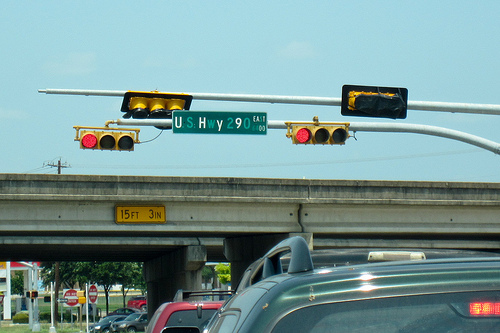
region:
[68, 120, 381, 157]
traffic lights are red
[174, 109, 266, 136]
road sign is green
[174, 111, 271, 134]
road sign is white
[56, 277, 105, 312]
sign under bridge is red and white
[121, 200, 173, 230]
sign on bridge is yellow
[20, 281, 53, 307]
pedestrian signs under bridge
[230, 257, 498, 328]
green van under traffic light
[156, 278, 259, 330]
red van under traffic light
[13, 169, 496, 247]
overpass is grey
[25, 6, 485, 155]
sky is mostly overcast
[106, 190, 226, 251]
Yellow sign on overpass.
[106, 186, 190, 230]
Black writing on yellow sign.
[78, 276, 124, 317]
Red and white do not enter sign.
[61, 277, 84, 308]
Red and white do not enter sign.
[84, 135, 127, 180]
Traffic light is on red.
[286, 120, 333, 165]
Traffic signal is on red light.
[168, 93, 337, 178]
Green and white street sign on pole.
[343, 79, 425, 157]
Traffic light is covered with black covering.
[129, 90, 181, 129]
Traffic light is covered with black cover.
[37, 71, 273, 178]
Sky is blue and clear.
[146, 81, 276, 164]
a street sign on a pole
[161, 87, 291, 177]
a street sign in the air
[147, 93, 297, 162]
a street sign on a metal pole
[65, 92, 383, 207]
a street sign in between two lights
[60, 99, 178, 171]
a traffic light in the air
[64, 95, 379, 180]
two traffic lights in the air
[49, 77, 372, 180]
two red traffic lights in the air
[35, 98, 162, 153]
a traffic light on a pole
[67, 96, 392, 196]
two traffic lights on a pole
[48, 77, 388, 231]
two traffic lights on a metal pole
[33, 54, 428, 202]
street lights attached to pole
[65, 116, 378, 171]
the streetlights are yellow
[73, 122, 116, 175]
the light is red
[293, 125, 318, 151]
the light is red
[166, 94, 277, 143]
the sign is green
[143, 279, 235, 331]
the car is red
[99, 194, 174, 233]
the sign is yellow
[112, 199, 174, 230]
black letters on sign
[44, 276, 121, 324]
signs are red and white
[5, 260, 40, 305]
the building is white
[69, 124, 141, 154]
an electric traffic signal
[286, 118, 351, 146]
an electric traffic signal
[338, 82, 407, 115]
an electric traffic signal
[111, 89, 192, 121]
an electric traffic signal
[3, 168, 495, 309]
a bridge over pass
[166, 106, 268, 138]
a green street sign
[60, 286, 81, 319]
a traffic do not enter sign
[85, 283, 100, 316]
a traffic do not enter sign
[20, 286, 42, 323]
electronic do not walk signs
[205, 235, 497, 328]
top of a minivan